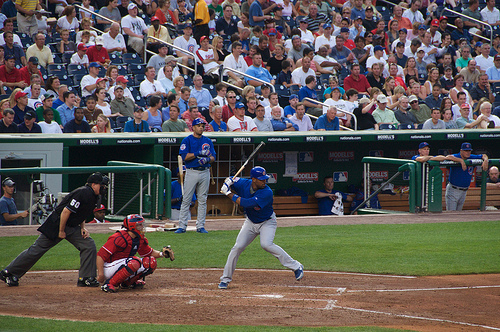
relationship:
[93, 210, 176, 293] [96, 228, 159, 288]
catcher wears uniform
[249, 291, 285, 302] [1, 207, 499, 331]
home plate on baseball field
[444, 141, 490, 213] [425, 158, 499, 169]
man leaning over rail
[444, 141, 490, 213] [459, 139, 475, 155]
man wearing hat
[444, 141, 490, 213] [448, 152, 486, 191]
man wears shirt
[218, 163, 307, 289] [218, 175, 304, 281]
batter wears uniform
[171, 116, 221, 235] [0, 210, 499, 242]
man on deck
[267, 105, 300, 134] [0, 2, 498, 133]
man in stands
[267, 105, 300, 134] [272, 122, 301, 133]
man has folded arms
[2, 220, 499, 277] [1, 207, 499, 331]
grass on baseball field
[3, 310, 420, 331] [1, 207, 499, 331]
grass on baseball field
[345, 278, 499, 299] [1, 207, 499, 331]
line on baseball field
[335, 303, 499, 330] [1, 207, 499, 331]
line on baseball field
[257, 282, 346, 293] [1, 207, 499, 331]
line on baseball field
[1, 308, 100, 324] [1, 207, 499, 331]
line on baseball field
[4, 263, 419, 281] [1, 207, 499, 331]
line on baseball field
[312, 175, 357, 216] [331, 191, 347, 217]
man has towel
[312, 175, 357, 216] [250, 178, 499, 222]
man on bench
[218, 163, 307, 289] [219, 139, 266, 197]
batter swings bat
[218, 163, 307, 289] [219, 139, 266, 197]
batter holds bat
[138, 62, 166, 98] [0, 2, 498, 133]
spectator in stands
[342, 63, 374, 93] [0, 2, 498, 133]
spectator in stands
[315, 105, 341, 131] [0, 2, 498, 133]
spectator in stands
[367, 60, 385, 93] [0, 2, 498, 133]
spectator in stands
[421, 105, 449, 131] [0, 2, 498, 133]
spectator in stands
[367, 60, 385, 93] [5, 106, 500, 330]
spectator watching baseball game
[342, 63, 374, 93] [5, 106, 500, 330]
spectator watching baseball game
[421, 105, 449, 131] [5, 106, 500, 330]
spectator watching baseball game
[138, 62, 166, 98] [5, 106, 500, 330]
spectator watching baseball game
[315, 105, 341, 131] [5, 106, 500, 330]
spectator watching baseball game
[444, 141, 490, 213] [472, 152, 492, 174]
man has arm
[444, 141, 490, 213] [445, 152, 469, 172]
man has arm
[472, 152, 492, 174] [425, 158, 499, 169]
arm on rail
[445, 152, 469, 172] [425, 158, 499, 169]
arm on rail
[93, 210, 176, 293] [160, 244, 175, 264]
catcher wears mitt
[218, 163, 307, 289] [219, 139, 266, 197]
batter swinging bat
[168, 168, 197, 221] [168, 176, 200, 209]
player wears jersey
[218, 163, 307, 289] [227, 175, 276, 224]
batter wears jersey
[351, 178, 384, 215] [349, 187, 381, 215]
player wears jersey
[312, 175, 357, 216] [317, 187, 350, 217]
man wears jersey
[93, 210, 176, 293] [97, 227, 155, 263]
catcher wearing jersey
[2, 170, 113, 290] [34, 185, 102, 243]
umpire wears shirt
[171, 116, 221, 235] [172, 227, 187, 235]
man wears spikes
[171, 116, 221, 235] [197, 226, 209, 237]
man wears spikes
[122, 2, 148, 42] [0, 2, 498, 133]
fan in stands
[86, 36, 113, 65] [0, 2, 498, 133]
fan in stands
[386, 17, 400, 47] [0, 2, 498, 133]
fan in stands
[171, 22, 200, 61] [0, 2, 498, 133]
fan in stands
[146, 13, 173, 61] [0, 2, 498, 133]
fan in stands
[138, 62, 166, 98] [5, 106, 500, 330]
spectator watches baseball game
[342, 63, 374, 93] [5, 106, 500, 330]
spectator watches baseball game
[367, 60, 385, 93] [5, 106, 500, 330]
spectator watches baseball game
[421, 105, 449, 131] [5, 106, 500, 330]
spectator watches baseball game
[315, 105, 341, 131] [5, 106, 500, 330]
spectator watches baseball game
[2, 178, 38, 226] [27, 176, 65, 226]
cameraman has camera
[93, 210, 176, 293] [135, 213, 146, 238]
catcher wears face mask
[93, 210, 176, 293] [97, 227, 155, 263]
catcher wears jersey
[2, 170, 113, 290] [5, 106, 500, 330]
umpire officiates baseball game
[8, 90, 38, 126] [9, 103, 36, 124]
man wears shirt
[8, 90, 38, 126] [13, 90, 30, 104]
man wears hat